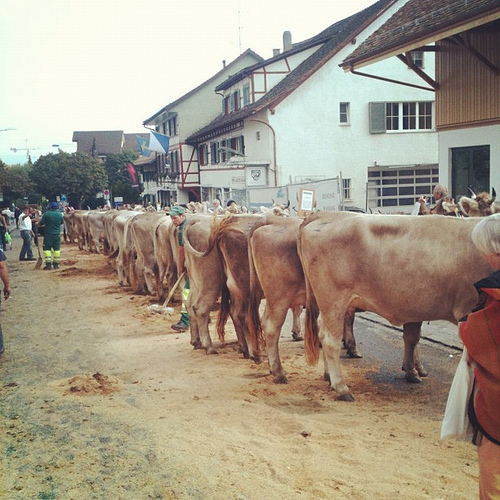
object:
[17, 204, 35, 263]
people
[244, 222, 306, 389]
cows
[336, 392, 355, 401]
hoof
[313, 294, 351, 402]
leg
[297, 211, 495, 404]
cow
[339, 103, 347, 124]
window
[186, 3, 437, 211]
home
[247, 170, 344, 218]
structure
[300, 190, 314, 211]
sign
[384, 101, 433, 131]
three windows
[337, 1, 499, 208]
building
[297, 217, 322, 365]
tail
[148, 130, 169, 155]
flag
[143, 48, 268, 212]
building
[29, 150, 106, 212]
trees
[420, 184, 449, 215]
person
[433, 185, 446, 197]
hair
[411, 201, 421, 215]
bag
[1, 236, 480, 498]
sand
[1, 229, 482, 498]
pavement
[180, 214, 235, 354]
cow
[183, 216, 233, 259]
tail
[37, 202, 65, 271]
person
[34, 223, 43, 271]
shovel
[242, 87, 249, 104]
windows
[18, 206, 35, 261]
man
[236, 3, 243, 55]
antenna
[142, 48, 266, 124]
rooftop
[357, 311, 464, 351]
sidewalk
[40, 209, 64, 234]
shirt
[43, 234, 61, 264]
pants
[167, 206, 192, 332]
man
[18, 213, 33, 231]
shirt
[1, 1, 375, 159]
sky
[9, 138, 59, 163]
crane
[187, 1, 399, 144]
rooftop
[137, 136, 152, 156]
flags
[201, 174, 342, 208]
fence